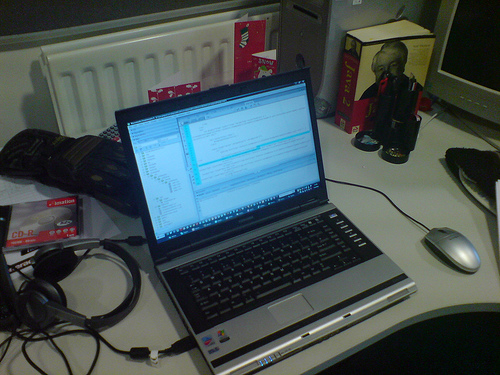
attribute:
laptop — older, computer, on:
[115, 69, 415, 374]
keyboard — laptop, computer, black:
[162, 210, 383, 334]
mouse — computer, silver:
[424, 227, 481, 274]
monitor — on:
[115, 69, 328, 260]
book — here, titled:
[332, 21, 437, 135]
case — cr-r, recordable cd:
[1, 193, 79, 254]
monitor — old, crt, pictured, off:
[419, 0, 498, 149]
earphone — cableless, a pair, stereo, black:
[14, 240, 142, 329]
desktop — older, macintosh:
[273, 0, 437, 119]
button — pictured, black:
[356, 240, 367, 248]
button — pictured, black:
[351, 235, 363, 245]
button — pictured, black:
[343, 227, 355, 235]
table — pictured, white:
[2, 104, 498, 373]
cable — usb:
[0, 262, 196, 374]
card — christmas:
[250, 48, 278, 83]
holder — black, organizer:
[353, 72, 422, 164]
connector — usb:
[171, 336, 197, 353]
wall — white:
[0, 3, 289, 165]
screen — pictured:
[126, 84, 318, 234]